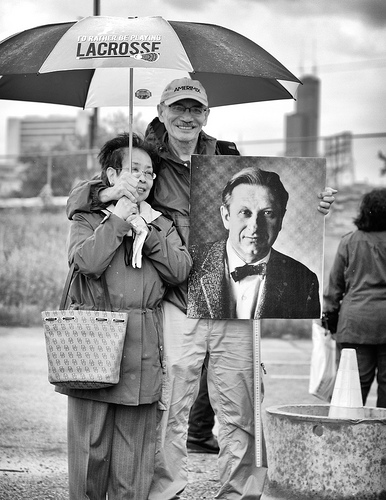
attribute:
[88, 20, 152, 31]
umbrella — white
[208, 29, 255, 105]
umbrella — black, wet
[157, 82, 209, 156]
man — old, smiling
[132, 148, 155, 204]
woman — old, looking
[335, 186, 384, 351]
person — standing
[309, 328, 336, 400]
bag — white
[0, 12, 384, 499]
image — black, white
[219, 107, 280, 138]
image — white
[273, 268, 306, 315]
image — black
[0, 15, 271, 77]
umbrella — open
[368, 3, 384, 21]
clouds — black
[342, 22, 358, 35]
clouds — white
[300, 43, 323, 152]
building — photo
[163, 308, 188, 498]
pants — wrinkled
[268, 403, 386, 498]
container — large, empty